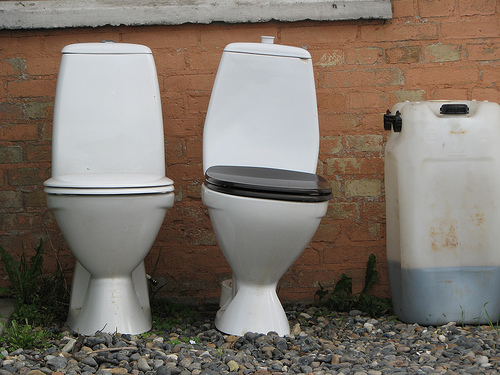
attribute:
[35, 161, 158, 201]
lid — white, black, plastic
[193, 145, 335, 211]
lid — black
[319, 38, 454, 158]
wall — peeling, red, brick, dirty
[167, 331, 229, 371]
gravel — gray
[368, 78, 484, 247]
container — plastic, quarter full, beisde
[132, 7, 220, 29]
ledge — gray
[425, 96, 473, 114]
cap — black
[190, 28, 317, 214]
toilet — white, porcelain, whiet, flushing, tilted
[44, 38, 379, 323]
toilets — sitting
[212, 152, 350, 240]
seat — white, black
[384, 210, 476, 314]
jug — liquid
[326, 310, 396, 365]
rocks — tiny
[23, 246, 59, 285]
plants — patchy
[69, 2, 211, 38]
window sill — here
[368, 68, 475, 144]
stopper — plastic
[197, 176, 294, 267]
bowl — white, toilet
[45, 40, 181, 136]
tank — white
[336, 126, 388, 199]
brick — orange